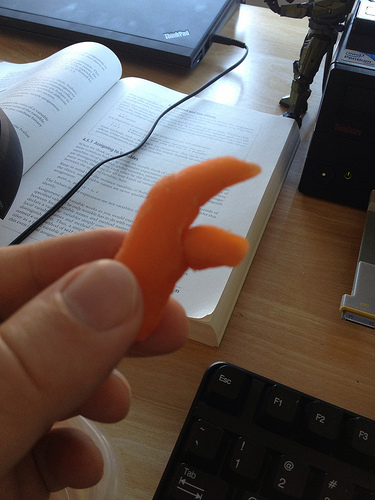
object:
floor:
[242, 11, 263, 39]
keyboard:
[151, 360, 374, 499]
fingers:
[0, 227, 189, 358]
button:
[344, 169, 354, 181]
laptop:
[1, 0, 235, 75]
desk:
[2, 6, 374, 499]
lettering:
[176, 373, 373, 499]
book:
[0, 40, 302, 349]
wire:
[7, 32, 249, 249]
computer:
[296, 0, 374, 211]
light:
[320, 171, 327, 179]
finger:
[0, 258, 145, 477]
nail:
[61, 258, 140, 336]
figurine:
[262, 0, 352, 132]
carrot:
[113, 155, 262, 344]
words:
[0, 46, 255, 294]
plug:
[339, 204, 374, 332]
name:
[163, 28, 190, 40]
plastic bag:
[43, 415, 121, 498]